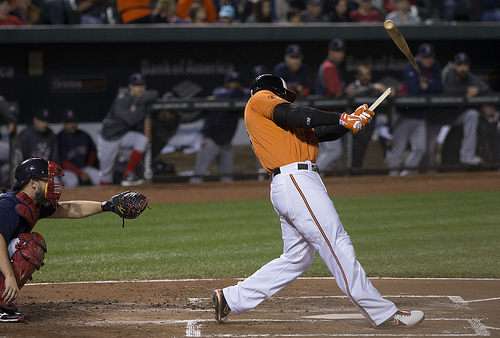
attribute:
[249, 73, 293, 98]
hat — black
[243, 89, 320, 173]
shirt — orange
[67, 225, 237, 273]
grass — green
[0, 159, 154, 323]
umpire — crouching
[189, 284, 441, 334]
shoes — orange, black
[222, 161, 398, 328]
pants — white, orange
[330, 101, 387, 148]
gloves — orange, white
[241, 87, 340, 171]
shirt — orange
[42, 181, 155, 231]
left arm — extended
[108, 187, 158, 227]
mitt — black, red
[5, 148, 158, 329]
catcher — crouched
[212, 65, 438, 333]
guy — holding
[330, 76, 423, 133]
bat — broken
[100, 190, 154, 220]
mit — black, red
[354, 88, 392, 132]
bat — breaking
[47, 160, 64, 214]
face mask — red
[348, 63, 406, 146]
bat — broken